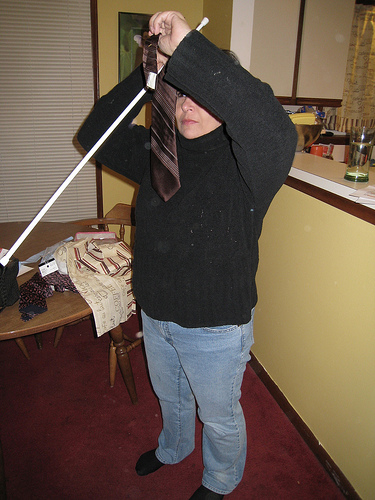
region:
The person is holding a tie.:
[139, 32, 181, 205]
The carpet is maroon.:
[15, 353, 289, 499]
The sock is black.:
[128, 437, 168, 472]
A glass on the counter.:
[339, 127, 373, 185]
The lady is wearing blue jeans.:
[129, 322, 253, 477]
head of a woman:
[149, 50, 247, 144]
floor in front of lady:
[7, 429, 105, 491]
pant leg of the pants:
[177, 370, 263, 494]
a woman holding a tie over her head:
[99, 19, 291, 499]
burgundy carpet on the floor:
[34, 402, 99, 473]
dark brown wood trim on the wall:
[294, 421, 313, 446]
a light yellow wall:
[302, 340, 347, 413]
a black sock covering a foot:
[126, 452, 160, 480]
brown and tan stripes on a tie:
[157, 106, 174, 171]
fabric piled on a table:
[64, 242, 134, 314]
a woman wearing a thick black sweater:
[81, 57, 265, 331]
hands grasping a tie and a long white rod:
[141, 43, 171, 65]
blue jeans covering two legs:
[138, 313, 245, 481]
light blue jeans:
[102, 276, 308, 498]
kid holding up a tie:
[75, 6, 284, 336]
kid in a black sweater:
[81, 36, 293, 350]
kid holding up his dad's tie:
[64, 19, 286, 398]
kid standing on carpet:
[45, 92, 366, 473]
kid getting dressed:
[48, 71, 306, 432]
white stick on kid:
[10, 12, 327, 343]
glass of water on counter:
[276, 77, 374, 206]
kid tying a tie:
[94, 33, 317, 424]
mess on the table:
[0, 197, 194, 367]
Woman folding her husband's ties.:
[76, 2, 292, 492]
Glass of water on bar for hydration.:
[343, 121, 374, 190]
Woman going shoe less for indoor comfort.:
[124, 424, 248, 499]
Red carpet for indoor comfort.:
[12, 376, 142, 493]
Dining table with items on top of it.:
[4, 202, 112, 353]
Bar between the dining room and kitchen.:
[283, 131, 373, 211]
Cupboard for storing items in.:
[253, 1, 353, 114]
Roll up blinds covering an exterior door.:
[0, 1, 97, 222]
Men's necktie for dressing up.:
[137, 31, 186, 208]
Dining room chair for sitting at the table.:
[63, 198, 147, 362]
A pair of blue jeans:
[132, 308, 264, 480]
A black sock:
[131, 446, 165, 479]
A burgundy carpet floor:
[10, 386, 130, 496]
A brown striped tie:
[132, 35, 188, 198]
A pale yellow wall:
[276, 218, 372, 387]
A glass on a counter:
[341, 122, 371, 183]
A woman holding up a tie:
[103, 21, 278, 244]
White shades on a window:
[1, 8, 92, 205]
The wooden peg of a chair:
[97, 315, 146, 405]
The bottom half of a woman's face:
[166, 83, 231, 139]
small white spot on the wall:
[309, 435, 325, 446]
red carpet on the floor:
[46, 413, 111, 458]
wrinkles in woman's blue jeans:
[196, 405, 243, 450]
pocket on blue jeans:
[188, 314, 250, 345]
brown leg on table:
[101, 340, 143, 394]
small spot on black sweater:
[161, 208, 277, 285]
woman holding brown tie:
[106, 20, 203, 188]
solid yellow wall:
[288, 241, 368, 336]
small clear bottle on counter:
[338, 120, 372, 183]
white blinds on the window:
[13, 26, 83, 161]